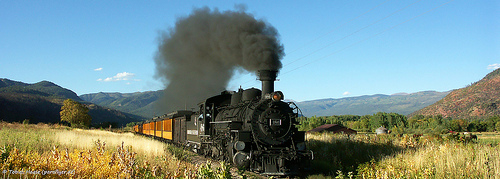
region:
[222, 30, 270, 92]
part of a smoke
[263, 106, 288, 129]
part of a budge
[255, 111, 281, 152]
part of a train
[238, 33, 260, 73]
part of a smoke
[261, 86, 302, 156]
part of a train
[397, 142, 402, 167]
part of a ground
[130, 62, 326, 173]
A train in the foreground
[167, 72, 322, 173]
A front view of a train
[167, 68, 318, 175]
The front of the train is black in color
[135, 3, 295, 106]
Smoke is coming off the train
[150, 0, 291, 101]
The smoke is gray in color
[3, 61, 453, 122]
Mountains in the background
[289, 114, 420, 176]
Train is casting a shadow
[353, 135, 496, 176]
Tall grass is dried out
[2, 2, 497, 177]
Photo was taken outdoors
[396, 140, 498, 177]
Grass is tan colored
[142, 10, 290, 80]
There is smoke coming out of train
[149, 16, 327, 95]
The smoke is black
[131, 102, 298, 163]
This is a train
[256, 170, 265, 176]
This is a train track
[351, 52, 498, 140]
These are mountains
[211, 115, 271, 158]
This is a black car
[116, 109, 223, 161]
These are train cars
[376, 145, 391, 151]
This is long grass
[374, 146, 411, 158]
The grass is yellow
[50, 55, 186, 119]
These are clouds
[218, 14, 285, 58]
A heavy train smoke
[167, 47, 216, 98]
A heavy train smoke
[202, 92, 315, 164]
A black train car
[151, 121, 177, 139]
An orange train cargo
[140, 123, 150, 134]
An orange train cargo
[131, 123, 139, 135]
An orange train cargo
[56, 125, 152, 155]
Brown dry grass on the train way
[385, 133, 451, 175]
Brown dry grass on the train way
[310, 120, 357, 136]
A brown roofed houde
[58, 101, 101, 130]
A big green tree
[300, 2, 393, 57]
this is the sky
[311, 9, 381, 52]
the sky is blue in color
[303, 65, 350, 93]
the sky has some clouds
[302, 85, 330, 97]
the clouds are white in color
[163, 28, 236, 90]
this is some smoke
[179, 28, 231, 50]
the smoke is black in color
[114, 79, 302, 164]
this is a train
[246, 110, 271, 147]
the train is black in color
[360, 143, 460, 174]
this is the grass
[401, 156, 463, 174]
the grass is short